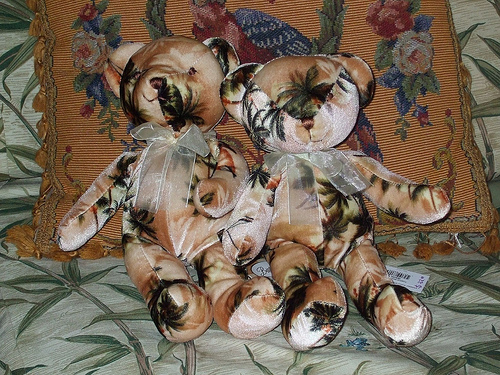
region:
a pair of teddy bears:
[58, 21, 478, 358]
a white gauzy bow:
[261, 133, 383, 253]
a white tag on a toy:
[222, 59, 449, 332]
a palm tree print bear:
[216, 52, 455, 355]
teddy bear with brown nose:
[217, 50, 384, 159]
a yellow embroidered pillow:
[34, 5, 488, 272]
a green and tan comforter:
[11, 238, 495, 351]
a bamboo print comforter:
[21, 239, 205, 368]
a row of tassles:
[389, 212, 499, 258]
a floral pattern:
[364, 2, 444, 132]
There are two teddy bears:
[58, 32, 428, 360]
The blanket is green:
[19, 94, 485, 362]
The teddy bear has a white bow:
[135, 112, 212, 226]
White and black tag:
[367, 248, 444, 308]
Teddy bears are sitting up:
[30, 14, 469, 339]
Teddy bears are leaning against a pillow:
[36, 21, 463, 345]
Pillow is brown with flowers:
[26, 12, 470, 286]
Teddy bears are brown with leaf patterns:
[82, 44, 439, 336]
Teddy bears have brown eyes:
[91, 32, 361, 141]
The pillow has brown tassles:
[8, 15, 488, 260]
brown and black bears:
[91, 37, 423, 339]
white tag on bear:
[339, 233, 426, 289]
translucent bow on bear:
[138, 107, 219, 221]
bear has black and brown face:
[108, 41, 237, 141]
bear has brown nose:
[137, 74, 176, 98]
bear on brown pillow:
[40, 11, 126, 151]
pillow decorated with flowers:
[67, 13, 117, 150]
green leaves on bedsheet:
[21, 252, 149, 372]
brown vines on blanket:
[11, 238, 150, 365]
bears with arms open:
[94, 23, 455, 351]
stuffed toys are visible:
[127, 94, 322, 368]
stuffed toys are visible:
[230, 142, 314, 370]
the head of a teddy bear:
[98, 30, 243, 135]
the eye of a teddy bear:
[180, 58, 203, 85]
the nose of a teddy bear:
[146, 72, 173, 91]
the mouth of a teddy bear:
[136, 87, 191, 109]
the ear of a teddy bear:
[98, 37, 150, 103]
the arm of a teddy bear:
[52, 146, 141, 256]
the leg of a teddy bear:
[118, 225, 218, 346]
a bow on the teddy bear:
[123, 114, 215, 222]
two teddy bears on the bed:
[48, 27, 454, 359]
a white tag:
[380, 255, 436, 296]